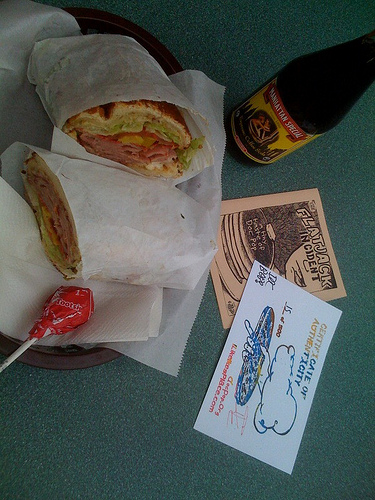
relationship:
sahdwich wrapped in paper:
[28, 34, 195, 185] [0, 0, 227, 377]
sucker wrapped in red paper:
[2, 282, 101, 380] [24, 280, 101, 347]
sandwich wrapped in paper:
[91, 110, 174, 166] [73, 50, 131, 97]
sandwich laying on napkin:
[35, 33, 197, 184] [0, 5, 227, 374]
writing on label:
[267, 84, 305, 140] [228, 75, 320, 166]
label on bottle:
[228, 75, 320, 166] [219, 26, 374, 165]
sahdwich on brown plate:
[28, 34, 195, 185] [1, 2, 199, 373]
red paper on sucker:
[24, 280, 101, 347] [1, 284, 96, 371]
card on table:
[193, 259, 343, 475] [1, 0, 374, 498]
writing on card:
[291, 348, 316, 399] [193, 259, 343, 475]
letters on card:
[285, 346, 318, 403] [193, 259, 343, 475]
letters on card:
[206, 341, 240, 416] [193, 259, 343, 475]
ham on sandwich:
[86, 130, 175, 162] [30, 33, 194, 175]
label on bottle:
[228, 75, 320, 166] [224, 28, 372, 174]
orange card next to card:
[211, 187, 348, 330] [193, 259, 343, 475]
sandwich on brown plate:
[18, 93, 204, 283] [1, 2, 199, 373]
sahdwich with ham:
[28, 34, 195, 185] [86, 130, 175, 162]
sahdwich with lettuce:
[28, 34, 195, 185] [182, 142, 203, 165]